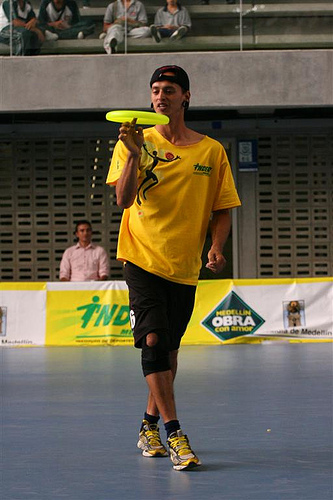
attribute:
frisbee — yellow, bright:
[104, 107, 171, 126]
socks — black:
[142, 409, 180, 432]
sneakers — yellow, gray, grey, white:
[135, 419, 199, 472]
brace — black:
[140, 327, 172, 378]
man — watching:
[59, 220, 110, 281]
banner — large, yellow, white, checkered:
[1, 276, 332, 347]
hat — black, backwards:
[148, 64, 190, 90]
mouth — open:
[156, 101, 169, 111]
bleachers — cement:
[3, 2, 332, 48]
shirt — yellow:
[105, 127, 240, 286]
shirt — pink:
[58, 239, 111, 282]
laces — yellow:
[146, 428, 188, 453]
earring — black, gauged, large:
[181, 99, 191, 110]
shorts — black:
[122, 260, 195, 349]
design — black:
[133, 139, 180, 208]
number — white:
[128, 304, 137, 329]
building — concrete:
[1, 0, 331, 280]